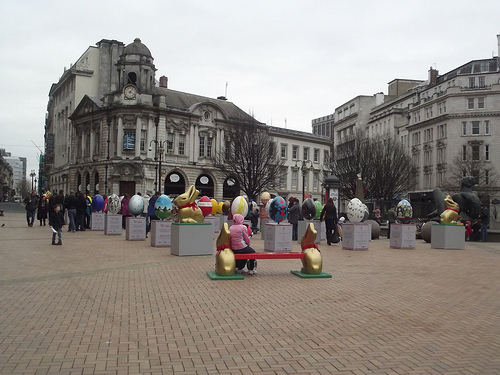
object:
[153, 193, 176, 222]
egg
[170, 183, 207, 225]
bunny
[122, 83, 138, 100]
clock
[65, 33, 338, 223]
building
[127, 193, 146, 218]
egg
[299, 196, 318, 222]
egg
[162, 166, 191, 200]
arches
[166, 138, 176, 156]
streetlamp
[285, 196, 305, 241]
group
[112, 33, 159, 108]
tower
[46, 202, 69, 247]
people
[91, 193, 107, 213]
egg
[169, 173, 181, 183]
clocks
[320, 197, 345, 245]
person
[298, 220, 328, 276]
bunny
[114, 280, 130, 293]
bricks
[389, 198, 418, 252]
statue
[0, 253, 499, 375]
sidewalk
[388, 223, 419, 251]
stand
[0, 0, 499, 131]
sky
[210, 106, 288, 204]
trees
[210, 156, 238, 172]
branches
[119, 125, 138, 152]
window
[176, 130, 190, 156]
window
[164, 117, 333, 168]
sections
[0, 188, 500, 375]
town square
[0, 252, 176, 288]
line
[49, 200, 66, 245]
person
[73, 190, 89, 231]
person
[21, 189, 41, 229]
person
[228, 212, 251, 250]
jacket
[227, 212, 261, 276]
woman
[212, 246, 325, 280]
bench